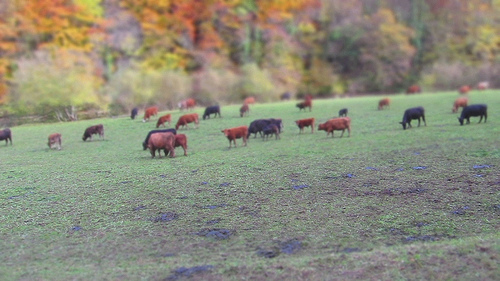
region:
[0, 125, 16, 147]
a cow eating grass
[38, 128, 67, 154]
a cow eating grass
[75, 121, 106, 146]
a cow eating grass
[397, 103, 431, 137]
a cow eating grass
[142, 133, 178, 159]
a cow eating grass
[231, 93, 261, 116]
a cow eating grass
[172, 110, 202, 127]
a cow eating grass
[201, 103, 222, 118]
a cow eating grass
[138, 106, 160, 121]
a cow eating grass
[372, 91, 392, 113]
a cow eating grass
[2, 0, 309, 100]
Autumn colored leaves on the tree.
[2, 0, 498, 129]
Trees in the background.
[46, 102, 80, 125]
Tree trunk on the tree.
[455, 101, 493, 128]
Cow eating the grass.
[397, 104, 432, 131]
Black cow on the grass.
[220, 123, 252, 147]
Young brown calf on the grass.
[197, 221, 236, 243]
Cow patty in the grass.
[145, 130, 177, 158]
Adult brown cow in the grass.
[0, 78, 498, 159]
Herd of cows in the grass.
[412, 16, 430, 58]
Green leaves on the tree.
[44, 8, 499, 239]
cows in a field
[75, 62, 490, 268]
a field with cows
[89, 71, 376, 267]
cows on the grass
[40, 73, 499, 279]
cows standing in a field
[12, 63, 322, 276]
cows standing in the grass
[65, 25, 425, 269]
cows standing on the grass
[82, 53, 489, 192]
a field of animals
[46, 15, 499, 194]
a field of different color cows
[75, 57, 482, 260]
cows walking in a field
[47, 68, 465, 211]
a field with walking cows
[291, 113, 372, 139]
There are brown cows on a field.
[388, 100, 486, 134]
There are black cows on a field.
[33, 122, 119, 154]
There are cows grazing on a field.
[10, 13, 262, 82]
There are multi colored trees near a field.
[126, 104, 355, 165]
There are a herd of cows on a field.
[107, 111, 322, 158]
A herd of cows grazing on a field.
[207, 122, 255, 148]
There is one cow looking in the opposite direction.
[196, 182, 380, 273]
There is green grass on a field.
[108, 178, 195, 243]
There is green grass on a field of cows.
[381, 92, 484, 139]
Cows are grazing on green grass on a field.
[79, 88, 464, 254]
a field walking on cows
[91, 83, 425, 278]
cows with a field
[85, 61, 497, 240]
cows walking on a field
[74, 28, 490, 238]
cows walking on grass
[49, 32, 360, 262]
cows walking on green grass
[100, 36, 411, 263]
cows standing on grass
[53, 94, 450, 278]
cows standing on green grass